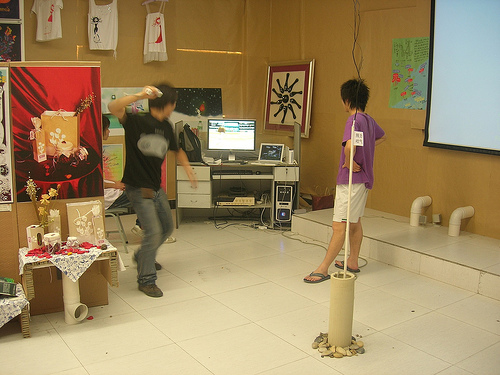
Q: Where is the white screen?
A: On the wall.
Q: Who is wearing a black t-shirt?
A: A man.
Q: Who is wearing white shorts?
A: The woman.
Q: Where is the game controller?
A: Man's hand.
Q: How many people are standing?
A: 2.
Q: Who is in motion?
A: The man with the game control.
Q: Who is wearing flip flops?
A: The standing woman.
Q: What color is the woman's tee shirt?
A: Purple.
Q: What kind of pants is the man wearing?
A: Blue jeans.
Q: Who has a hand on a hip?
A: Standing woman.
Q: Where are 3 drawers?
A: On desk.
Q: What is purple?
A: Boy's shirt.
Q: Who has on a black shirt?
A: Boy on left.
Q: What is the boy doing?
A: Playing video game.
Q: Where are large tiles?
A: On the floor.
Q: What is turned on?
A: Computer screen.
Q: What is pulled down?
A: A screen.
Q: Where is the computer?
A: On a desk.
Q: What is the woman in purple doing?
A: Standing.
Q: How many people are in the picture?
A: Two.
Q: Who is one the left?
A: A man.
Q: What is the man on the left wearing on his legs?
A: Jeans.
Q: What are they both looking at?
A: A screen.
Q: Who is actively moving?
A: The man.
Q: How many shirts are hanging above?
A: Three.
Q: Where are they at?
A: Art studio.